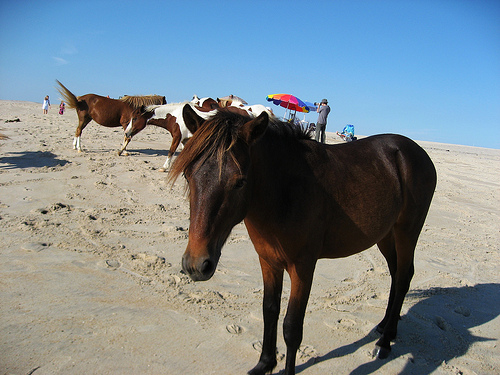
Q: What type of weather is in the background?
A: It is clear.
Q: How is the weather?
A: It is clear.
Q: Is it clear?
A: Yes, it is clear.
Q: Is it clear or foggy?
A: It is clear.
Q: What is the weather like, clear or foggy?
A: It is clear.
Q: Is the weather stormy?
A: No, it is clear.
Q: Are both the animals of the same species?
A: Yes, all the animals are horses.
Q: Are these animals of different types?
A: No, all the animals are horses.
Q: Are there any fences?
A: No, there are no fences.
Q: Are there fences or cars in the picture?
A: No, there are no fences or cars.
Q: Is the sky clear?
A: Yes, the sky is clear.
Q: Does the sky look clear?
A: Yes, the sky is clear.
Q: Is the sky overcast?
A: No, the sky is clear.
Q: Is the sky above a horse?
A: Yes, the sky is above a horse.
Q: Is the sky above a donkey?
A: No, the sky is above a horse.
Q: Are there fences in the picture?
A: No, there are no fences.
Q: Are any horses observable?
A: Yes, there is a horse.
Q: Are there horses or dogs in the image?
A: Yes, there is a horse.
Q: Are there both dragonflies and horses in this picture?
A: No, there is a horse but no dragonflies.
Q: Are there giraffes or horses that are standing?
A: Yes, the horse is standing.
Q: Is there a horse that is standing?
A: Yes, there is a horse that is standing.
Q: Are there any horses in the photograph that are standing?
A: Yes, there is a horse that is standing.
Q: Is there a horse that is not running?
A: Yes, there is a horse that is standing.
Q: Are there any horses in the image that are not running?
A: Yes, there is a horse that is standing.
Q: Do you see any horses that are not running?
A: Yes, there is a horse that is standing .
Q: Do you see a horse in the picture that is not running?
A: Yes, there is a horse that is standing .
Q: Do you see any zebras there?
A: No, there are no zebras.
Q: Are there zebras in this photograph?
A: No, there are no zebras.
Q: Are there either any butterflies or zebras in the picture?
A: No, there are no zebras or butterflies.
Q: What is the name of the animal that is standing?
A: The animal is a horse.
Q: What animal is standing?
A: The animal is a horse.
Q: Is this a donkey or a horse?
A: This is a horse.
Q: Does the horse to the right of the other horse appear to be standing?
A: Yes, the horse is standing.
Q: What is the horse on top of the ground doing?
A: The horse is standing.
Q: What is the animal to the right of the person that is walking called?
A: The animal is a horse.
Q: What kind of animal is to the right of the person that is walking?
A: The animal is a horse.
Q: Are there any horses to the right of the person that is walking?
A: Yes, there is a horse to the right of the person.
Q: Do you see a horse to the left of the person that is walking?
A: No, the horse is to the right of the person.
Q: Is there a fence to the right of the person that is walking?
A: No, there is a horse to the right of the person.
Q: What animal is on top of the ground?
A: The horse is on top of the ground.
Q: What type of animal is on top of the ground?
A: The animal is a horse.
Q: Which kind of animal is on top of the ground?
A: The animal is a horse.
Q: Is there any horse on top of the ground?
A: Yes, there is a horse on top of the ground.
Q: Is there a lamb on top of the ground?
A: No, there is a horse on top of the ground.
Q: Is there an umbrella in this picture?
A: Yes, there is an umbrella.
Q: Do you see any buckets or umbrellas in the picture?
A: Yes, there is an umbrella.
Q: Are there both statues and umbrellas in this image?
A: No, there is an umbrella but no statues.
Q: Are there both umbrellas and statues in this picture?
A: No, there is an umbrella but no statues.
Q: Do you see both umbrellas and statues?
A: No, there is an umbrella but no statues.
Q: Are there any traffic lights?
A: No, there are no traffic lights.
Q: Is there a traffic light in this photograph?
A: No, there are no traffic lights.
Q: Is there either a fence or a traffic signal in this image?
A: No, there are no traffic lights or fences.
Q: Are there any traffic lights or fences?
A: No, there are no traffic lights or fences.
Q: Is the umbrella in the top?
A: Yes, the umbrella is in the top of the image.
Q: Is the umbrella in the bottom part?
A: No, the umbrella is in the top of the image.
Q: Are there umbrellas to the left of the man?
A: Yes, there is an umbrella to the left of the man.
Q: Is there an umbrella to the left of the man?
A: Yes, there is an umbrella to the left of the man.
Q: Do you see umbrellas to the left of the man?
A: Yes, there is an umbrella to the left of the man.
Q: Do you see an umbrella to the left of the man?
A: Yes, there is an umbrella to the left of the man.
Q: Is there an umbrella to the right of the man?
A: No, the umbrella is to the left of the man.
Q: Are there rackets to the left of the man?
A: No, there is an umbrella to the left of the man.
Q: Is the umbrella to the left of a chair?
A: No, the umbrella is to the left of the man.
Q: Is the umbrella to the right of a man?
A: No, the umbrella is to the left of a man.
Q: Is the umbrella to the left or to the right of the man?
A: The umbrella is to the left of the man.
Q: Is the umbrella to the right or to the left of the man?
A: The umbrella is to the left of the man.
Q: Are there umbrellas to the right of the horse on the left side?
A: Yes, there is an umbrella to the right of the horse.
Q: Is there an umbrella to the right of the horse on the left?
A: Yes, there is an umbrella to the right of the horse.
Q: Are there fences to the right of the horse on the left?
A: No, there is an umbrella to the right of the horse.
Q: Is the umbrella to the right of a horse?
A: Yes, the umbrella is to the right of a horse.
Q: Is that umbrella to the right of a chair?
A: No, the umbrella is to the right of a horse.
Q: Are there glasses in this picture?
A: No, there are no glasses.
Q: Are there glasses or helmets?
A: No, there are no glasses or helmets.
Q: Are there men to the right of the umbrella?
A: Yes, there is a man to the right of the umbrella.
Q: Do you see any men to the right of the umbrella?
A: Yes, there is a man to the right of the umbrella.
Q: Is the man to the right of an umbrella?
A: Yes, the man is to the right of an umbrella.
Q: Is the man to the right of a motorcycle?
A: No, the man is to the right of an umbrella.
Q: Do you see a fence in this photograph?
A: No, there are no fences.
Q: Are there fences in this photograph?
A: No, there are no fences.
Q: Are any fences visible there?
A: No, there are no fences.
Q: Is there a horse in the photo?
A: Yes, there is a horse.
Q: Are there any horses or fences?
A: Yes, there is a horse.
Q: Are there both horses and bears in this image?
A: No, there is a horse but no bears.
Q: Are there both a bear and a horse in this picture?
A: No, there is a horse but no bears.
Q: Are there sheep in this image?
A: No, there are no sheep.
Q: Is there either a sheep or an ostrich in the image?
A: No, there are no sheep or ostriches.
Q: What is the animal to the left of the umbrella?
A: The animal is a horse.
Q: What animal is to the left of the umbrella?
A: The animal is a horse.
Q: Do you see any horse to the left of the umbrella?
A: Yes, there is a horse to the left of the umbrella.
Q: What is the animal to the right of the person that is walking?
A: The animal is a horse.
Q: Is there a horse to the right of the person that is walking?
A: Yes, there is a horse to the right of the person.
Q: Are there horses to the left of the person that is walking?
A: No, the horse is to the right of the person.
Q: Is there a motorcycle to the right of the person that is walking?
A: No, there is a horse to the right of the person.